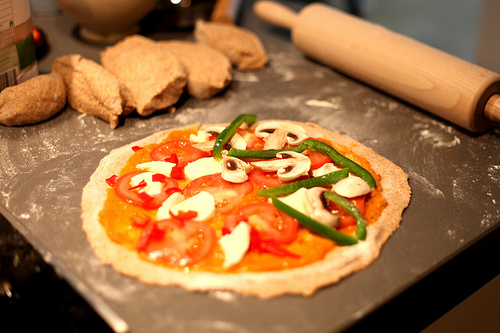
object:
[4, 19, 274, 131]
lumps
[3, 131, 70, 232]
flour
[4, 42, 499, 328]
surface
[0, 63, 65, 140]
lump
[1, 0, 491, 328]
photo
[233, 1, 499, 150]
roller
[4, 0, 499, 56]
background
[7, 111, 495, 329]
foreground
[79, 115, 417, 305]
dough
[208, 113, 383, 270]
vegetables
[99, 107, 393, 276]
toppings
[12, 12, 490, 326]
counter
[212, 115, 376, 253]
pepper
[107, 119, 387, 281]
tomatoes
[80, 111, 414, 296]
pizza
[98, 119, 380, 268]
sauce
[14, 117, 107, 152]
flour